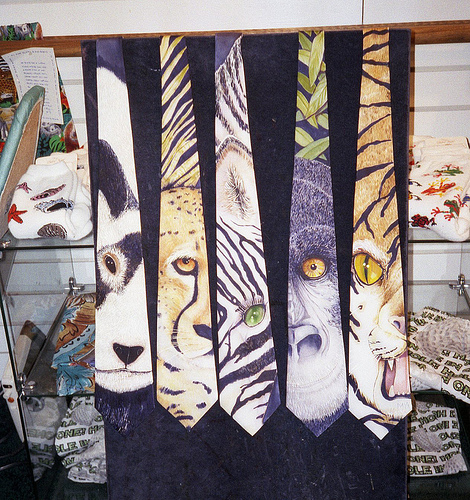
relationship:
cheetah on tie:
[162, 170, 207, 411] [157, 24, 213, 440]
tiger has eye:
[340, 28, 414, 439] [350, 243, 389, 295]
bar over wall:
[0, 20, 467, 219] [0, 0, 468, 495]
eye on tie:
[175, 257, 195, 271] [156, 34, 220, 434]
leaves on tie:
[293, 30, 329, 160] [284, 29, 351, 438]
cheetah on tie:
[156, 32, 218, 433] [149, 34, 220, 432]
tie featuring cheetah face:
[156, 34, 220, 434] [160, 185, 213, 372]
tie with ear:
[214, 33, 283, 438] [217, 137, 258, 221]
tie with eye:
[214, 33, 283, 438] [241, 301, 268, 326]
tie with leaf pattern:
[284, 29, 351, 438] [292, 26, 331, 166]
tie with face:
[284, 29, 351, 438] [284, 155, 348, 422]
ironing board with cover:
[1, 85, 41, 245] [0, 84, 46, 198]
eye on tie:
[95, 244, 128, 294] [88, 36, 153, 438]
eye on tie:
[170, 257, 198, 276] [156, 34, 220, 434]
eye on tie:
[242, 303, 267, 328] [214, 33, 280, 436]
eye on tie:
[299, 255, 329, 281] [284, 29, 351, 438]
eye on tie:
[352, 252, 386, 286] [345, 27, 412, 443]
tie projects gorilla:
[284, 29, 351, 438] [294, 145, 348, 435]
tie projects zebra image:
[214, 33, 280, 436] [216, 41, 278, 434]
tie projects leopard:
[156, 34, 220, 434] [140, 140, 224, 430]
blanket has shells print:
[6, 145, 93, 242] [6, 180, 73, 238]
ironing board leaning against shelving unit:
[0, 82, 47, 249] [0, 228, 106, 477]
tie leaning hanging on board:
[214, 33, 283, 438] [78, 27, 418, 498]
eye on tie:
[97, 242, 130, 291] [93, 35, 153, 394]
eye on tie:
[297, 251, 328, 280] [284, 29, 351, 438]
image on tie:
[341, 196, 410, 395] [345, 27, 412, 443]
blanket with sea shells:
[1, 60, 92, 240] [9, 145, 91, 241]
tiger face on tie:
[348, 186, 412, 406] [330, 0, 400, 361]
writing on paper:
[15, 56, 52, 114] [2, 44, 64, 129]